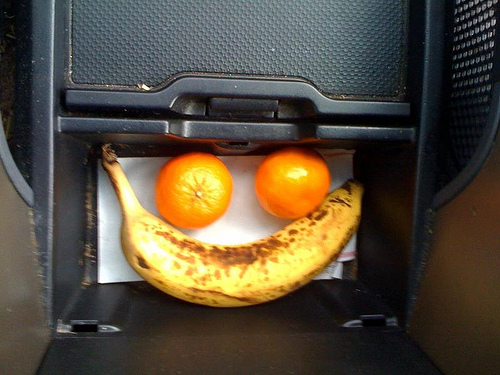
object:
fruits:
[99, 141, 372, 307]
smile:
[94, 139, 361, 304]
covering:
[66, 2, 416, 108]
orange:
[152, 154, 229, 229]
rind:
[160, 151, 231, 226]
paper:
[101, 155, 351, 294]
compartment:
[46, 10, 416, 135]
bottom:
[38, 131, 428, 328]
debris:
[80, 171, 109, 294]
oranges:
[156, 149, 332, 222]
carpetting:
[1, 199, 68, 347]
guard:
[75, 110, 414, 173]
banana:
[102, 151, 366, 317]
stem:
[95, 143, 136, 209]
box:
[2, 1, 499, 348]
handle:
[205, 95, 289, 122]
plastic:
[2, 0, 498, 215]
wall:
[2, 183, 499, 353]